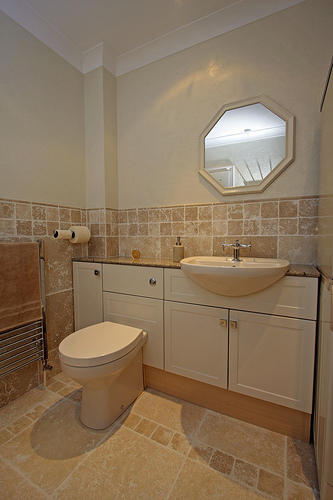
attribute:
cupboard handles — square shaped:
[213, 314, 240, 330]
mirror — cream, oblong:
[196, 93, 296, 194]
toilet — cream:
[45, 269, 153, 431]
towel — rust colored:
[4, 239, 44, 330]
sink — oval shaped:
[178, 250, 291, 301]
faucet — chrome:
[219, 238, 254, 259]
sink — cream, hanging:
[180, 254, 291, 300]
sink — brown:
[179, 254, 290, 295]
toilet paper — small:
[53, 227, 72, 242]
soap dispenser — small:
[172, 231, 185, 261]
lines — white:
[112, 416, 293, 498]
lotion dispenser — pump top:
[168, 234, 185, 260]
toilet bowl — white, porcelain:
[54, 317, 159, 410]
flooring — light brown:
[18, 431, 253, 483]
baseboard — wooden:
[142, 363, 311, 444]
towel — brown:
[0, 240, 42, 332]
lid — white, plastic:
[56, 319, 143, 367]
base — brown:
[143, 365, 310, 440]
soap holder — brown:
[156, 221, 187, 279]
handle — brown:
[218, 317, 226, 327]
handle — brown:
[229, 320, 238, 329]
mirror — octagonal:
[193, 91, 307, 199]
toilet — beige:
[50, 301, 167, 430]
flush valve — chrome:
[146, 275, 158, 287]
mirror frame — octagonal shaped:
[197, 92, 296, 198]